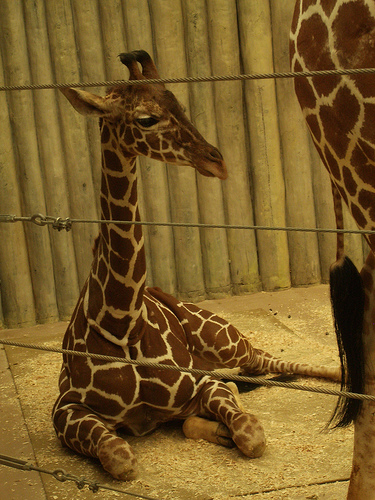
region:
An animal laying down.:
[26, 27, 361, 494]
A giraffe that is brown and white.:
[23, 31, 365, 498]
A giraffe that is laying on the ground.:
[33, 43, 365, 487]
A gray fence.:
[4, 203, 372, 435]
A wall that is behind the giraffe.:
[4, 3, 368, 297]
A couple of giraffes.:
[40, 4, 372, 496]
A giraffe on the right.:
[258, 1, 373, 498]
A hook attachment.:
[44, 450, 107, 498]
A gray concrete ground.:
[9, 319, 370, 496]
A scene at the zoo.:
[7, 11, 360, 483]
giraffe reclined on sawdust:
[58, 96, 268, 482]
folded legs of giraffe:
[42, 405, 142, 475]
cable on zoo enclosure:
[171, 358, 285, 395]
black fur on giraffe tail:
[314, 251, 367, 431]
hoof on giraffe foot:
[207, 416, 237, 451]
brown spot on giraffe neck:
[100, 265, 141, 317]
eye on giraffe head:
[130, 110, 168, 134]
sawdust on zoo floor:
[254, 457, 317, 498]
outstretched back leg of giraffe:
[242, 337, 334, 388]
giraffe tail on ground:
[235, 364, 302, 392]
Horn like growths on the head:
[80, 49, 186, 86]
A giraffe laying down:
[34, 51, 357, 472]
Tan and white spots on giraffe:
[81, 280, 230, 400]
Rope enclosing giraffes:
[3, 209, 373, 412]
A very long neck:
[68, 158, 154, 342]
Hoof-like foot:
[178, 414, 240, 452]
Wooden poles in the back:
[0, 2, 326, 280]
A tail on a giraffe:
[328, 174, 368, 440]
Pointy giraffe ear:
[56, 77, 122, 138]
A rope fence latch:
[6, 199, 96, 244]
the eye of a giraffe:
[129, 108, 162, 131]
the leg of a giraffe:
[44, 398, 143, 482]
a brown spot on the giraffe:
[104, 171, 131, 201]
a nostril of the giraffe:
[206, 143, 227, 163]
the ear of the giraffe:
[55, 81, 116, 119]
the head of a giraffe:
[51, 49, 234, 182]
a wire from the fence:
[0, 330, 373, 403]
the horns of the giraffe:
[115, 45, 161, 80]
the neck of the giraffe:
[76, 125, 157, 345]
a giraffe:
[43, 45, 359, 482]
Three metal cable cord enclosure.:
[0, 213, 374, 499]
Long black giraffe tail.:
[317, 251, 370, 432]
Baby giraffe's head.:
[52, 44, 230, 185]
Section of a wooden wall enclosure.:
[194, 26, 292, 118]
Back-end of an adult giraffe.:
[291, 1, 373, 248]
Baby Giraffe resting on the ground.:
[44, 41, 352, 481]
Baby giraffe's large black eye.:
[130, 112, 158, 131]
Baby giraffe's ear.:
[57, 85, 114, 118]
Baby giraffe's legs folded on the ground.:
[54, 383, 270, 481]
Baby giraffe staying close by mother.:
[53, 49, 349, 478]